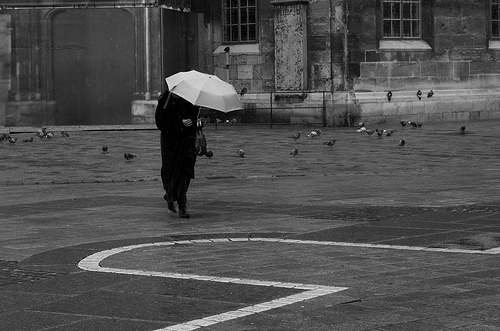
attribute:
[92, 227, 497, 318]
white line — white 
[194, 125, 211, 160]
bag — small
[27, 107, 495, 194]
road — cobblestone 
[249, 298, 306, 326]
bird poop — bird 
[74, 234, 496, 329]
line — white 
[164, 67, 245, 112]
umbrella — opened  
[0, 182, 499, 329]
walkway — Wet cement walk 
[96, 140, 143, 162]
pigeons — two dark 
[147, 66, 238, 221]
person — walking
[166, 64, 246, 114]
umbrella — white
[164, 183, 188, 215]
boots — black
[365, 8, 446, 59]
wall — stone 